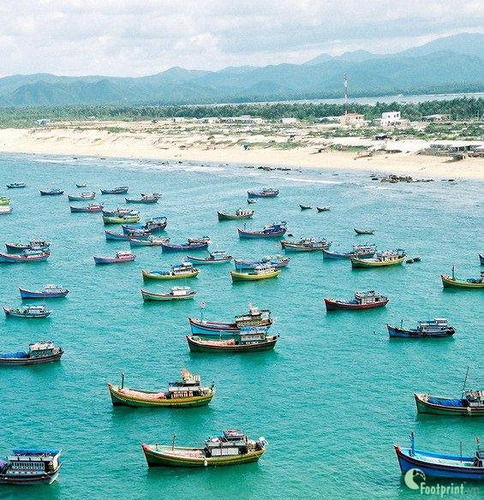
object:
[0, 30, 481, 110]
mountains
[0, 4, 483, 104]
background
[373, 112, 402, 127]
buildings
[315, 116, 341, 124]
buildings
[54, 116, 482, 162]
grass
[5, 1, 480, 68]
blue sky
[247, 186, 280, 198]
boats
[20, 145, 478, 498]
ripples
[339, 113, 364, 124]
buildings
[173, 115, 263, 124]
buildings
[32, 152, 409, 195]
waves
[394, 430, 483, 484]
blue boat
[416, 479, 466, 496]
credit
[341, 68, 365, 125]
tower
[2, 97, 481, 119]
trees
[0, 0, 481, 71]
sky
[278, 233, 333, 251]
boat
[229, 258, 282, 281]
boat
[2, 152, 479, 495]
water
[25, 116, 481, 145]
seaweed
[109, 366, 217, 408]
boat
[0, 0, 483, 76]
clouds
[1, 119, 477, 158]
sand/beach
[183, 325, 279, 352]
fishing boat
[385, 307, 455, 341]
fishing boat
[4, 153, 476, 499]
ocean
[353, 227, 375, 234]
small boats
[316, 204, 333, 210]
small boats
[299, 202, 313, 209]
small boats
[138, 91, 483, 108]
water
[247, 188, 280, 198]
boat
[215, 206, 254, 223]
boat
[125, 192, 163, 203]
boat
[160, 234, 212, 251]
boat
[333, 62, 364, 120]
satellite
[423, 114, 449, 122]
buildings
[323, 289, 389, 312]
boat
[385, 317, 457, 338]
boat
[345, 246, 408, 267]
boat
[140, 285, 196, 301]
boat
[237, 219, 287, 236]
boat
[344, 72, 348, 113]
pole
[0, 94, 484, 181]
beach